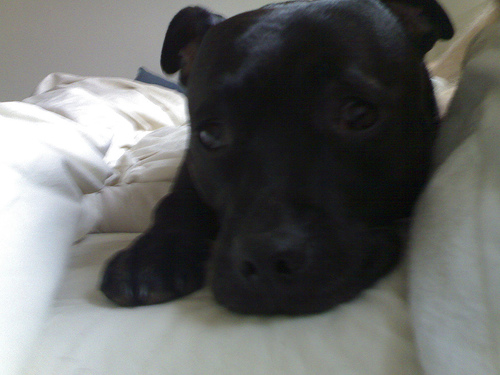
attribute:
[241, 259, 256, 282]
nostril — black, round hole, shadowed, blurry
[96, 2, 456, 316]
dog — large, shaggy, black, blurry, cute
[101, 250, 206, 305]
paw — black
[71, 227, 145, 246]
crease — white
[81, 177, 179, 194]
crease — white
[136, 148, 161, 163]
crease — white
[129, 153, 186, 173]
crease — white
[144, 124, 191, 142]
crease — white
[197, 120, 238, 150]
eye — black, dark, sad, reflecting light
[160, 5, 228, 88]
ear — black, floppy, curled, sweet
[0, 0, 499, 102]
wall — light gray, background, gray, white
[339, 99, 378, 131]
eye — dark, sad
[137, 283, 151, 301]
nail — reflective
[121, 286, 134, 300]
nail — reflective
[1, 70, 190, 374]
bedding — white, crumpled, reflective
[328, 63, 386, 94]
puppy eyebrow — slightly lighter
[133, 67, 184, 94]
pillow — distant, dark colored, background, dark blue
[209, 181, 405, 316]
muzzle — small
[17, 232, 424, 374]
sheet — white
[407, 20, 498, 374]
pillow — white